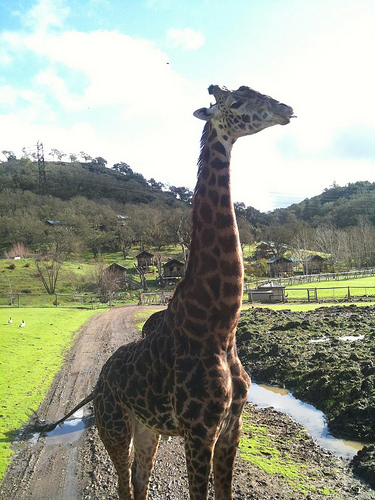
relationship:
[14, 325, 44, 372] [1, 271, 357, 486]
grass in a field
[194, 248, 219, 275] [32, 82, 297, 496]
spot on giraffe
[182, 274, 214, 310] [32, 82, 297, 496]
spot on giraffe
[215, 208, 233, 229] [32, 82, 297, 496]
spot on giraffe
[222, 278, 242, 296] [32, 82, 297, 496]
spot on giraffe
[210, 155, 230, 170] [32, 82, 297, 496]
spot on giraffe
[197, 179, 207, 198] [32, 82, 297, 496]
spot on giraffe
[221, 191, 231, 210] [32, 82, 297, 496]
spot on giraffe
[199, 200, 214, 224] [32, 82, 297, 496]
spot on giraffe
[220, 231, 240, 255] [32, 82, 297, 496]
spot on giraffe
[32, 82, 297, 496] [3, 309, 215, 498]
giraffe standing on road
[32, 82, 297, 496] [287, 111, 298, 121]
giraffe has tongue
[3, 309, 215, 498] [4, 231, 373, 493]
road in field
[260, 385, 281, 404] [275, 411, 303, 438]
water in mud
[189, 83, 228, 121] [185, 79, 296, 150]
horns on head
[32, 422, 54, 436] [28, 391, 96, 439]
hairs on tail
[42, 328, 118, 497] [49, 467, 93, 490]
tracks in mud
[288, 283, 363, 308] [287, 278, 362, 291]
fence in pen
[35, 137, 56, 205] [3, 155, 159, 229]
pole in hill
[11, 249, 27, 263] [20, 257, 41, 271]
animals in grass